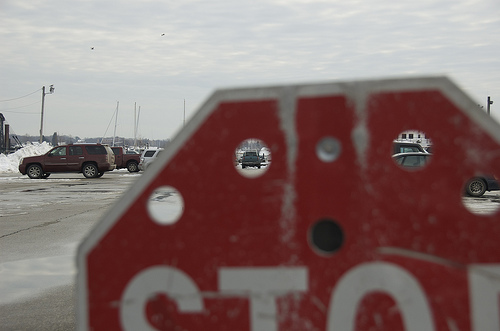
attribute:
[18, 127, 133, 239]
sport truck — white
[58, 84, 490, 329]
sign — red, white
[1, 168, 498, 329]
ground — grey, paved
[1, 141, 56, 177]
snow — white, cold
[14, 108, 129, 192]
vehicle — white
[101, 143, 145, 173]
pick-up — red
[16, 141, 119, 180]
suv — maroon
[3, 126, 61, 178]
snow — plowed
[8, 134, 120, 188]
vehicle — burgundy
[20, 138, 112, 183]
suv — maroon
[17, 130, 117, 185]
vehicle — maroon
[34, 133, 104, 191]
car — dark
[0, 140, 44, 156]
snow — white, cold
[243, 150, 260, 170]
suv — blue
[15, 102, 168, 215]
truck — dark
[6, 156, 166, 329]
road — paved, wet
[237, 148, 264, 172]
truck — blue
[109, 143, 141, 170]
truck — red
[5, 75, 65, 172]
pole — tall, grey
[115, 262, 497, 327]
lettering — white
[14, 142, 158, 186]
cars — winter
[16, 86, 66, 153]
pole — tall, wooden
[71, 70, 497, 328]
stop sign — red, white